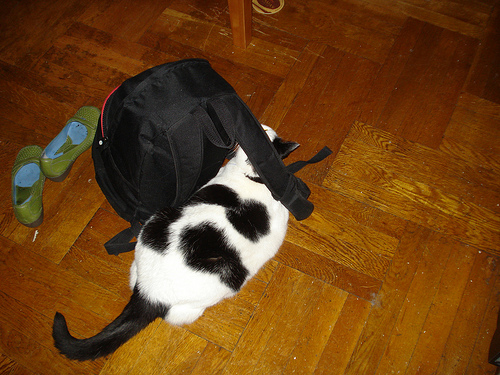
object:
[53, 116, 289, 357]
cat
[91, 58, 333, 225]
bag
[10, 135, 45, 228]
shoe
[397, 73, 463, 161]
floor